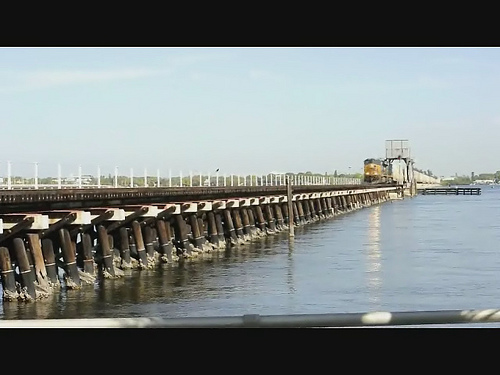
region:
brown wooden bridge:
[26, 168, 334, 248]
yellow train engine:
[367, 153, 388, 191]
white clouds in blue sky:
[32, 84, 71, 126]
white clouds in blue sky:
[101, 93, 148, 133]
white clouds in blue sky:
[248, 103, 289, 160]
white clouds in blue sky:
[93, 82, 144, 124]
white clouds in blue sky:
[335, 87, 378, 130]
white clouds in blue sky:
[411, 73, 454, 118]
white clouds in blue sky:
[210, 73, 249, 115]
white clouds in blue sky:
[119, 85, 172, 154]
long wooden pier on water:
[55, 166, 370, 261]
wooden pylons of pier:
[65, 230, 140, 281]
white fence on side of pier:
[44, 165, 97, 185]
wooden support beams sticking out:
[52, 209, 81, 234]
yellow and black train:
[357, 155, 389, 176]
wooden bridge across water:
[106, 183, 263, 265]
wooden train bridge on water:
[67, 178, 266, 278]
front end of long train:
[358, 150, 383, 178]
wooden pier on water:
[415, 186, 476, 196]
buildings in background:
[60, 168, 101, 185]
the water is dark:
[376, 206, 464, 276]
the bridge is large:
[77, 183, 410, 277]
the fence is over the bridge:
[89, 168, 360, 184]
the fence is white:
[21, 171, 307, 187]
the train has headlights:
[361, 169, 383, 180]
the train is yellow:
[363, 156, 384, 181]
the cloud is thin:
[42, 64, 174, 89]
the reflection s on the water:
[356, 209, 390, 299]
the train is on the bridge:
[325, 140, 449, 197]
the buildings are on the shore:
[433, 159, 495, 180]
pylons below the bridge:
[15, 225, 210, 277]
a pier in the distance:
[428, 183, 495, 195]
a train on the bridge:
[342, 140, 409, 199]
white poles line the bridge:
[32, 159, 174, 197]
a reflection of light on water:
[366, 196, 394, 301]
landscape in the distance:
[438, 170, 497, 189]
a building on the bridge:
[380, 125, 425, 202]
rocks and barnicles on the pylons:
[0, 230, 248, 304]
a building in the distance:
[47, 166, 98, 189]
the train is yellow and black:
[336, 125, 411, 216]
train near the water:
[362, 155, 396, 184]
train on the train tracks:
[360, 153, 390, 188]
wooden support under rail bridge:
[11, 234, 38, 301]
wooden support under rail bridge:
[33, 233, 61, 295]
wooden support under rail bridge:
[77, 231, 97, 283]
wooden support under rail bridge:
[92, 226, 120, 282]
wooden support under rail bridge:
[114, 228, 136, 279]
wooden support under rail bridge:
[130, 223, 152, 273]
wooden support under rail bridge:
[151, 217, 176, 269]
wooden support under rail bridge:
[185, 212, 210, 256]